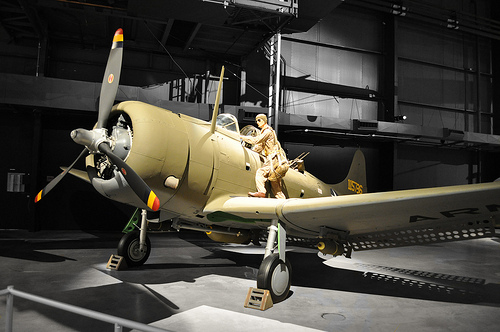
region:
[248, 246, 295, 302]
Wheel on a plane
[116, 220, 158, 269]
Black wheel on a plane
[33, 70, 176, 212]
Black prop on a plane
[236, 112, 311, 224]
Man standing on a wing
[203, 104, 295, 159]
Cockpit on a plane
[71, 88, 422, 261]
Tan plane in a hanger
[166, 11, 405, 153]
Gray wall in a hanger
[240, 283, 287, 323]
Block by a plane wheel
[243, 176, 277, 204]
Foot on a man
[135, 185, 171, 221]
Red, yellow and black on a propeller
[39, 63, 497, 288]
an old fighter jet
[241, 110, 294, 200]
a fake pilot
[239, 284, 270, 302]
a wedge preventing the plane from moving on the left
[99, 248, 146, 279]
a wedge preventing the plane from moving on the right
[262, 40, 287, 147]
a steel ladder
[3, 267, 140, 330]
some guard railing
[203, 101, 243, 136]
windshield on the plane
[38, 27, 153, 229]
propeller on the plane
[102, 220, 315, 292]
wheels on the plane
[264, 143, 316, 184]
a bag strapped to the fake pilot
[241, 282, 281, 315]
wheel stop blocks under wheel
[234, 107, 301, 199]
mannequin on an old airplane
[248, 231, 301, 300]
wheel on an old airplane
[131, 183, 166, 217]
red and yellow stripes on propellers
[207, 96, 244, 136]
windshield for cockpit on plane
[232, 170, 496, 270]
wing of airplane in hangar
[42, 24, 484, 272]
antique airplane with mannequin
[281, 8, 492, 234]
two story garage doors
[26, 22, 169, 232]
black propeller with stripes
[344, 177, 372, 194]
yellow numbers on tail fin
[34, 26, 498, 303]
an old fashioned beige plane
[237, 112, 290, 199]
statue of man climbing into plane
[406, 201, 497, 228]
large black lettering on bottom of wing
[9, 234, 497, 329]
grey floor with shadows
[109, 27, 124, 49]
red, black and yellow stripe on tip of propeller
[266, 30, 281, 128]
long silver ladder behind plane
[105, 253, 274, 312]
blocks keeping wheels in place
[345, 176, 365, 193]
yellow writing on tail fin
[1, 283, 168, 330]
part of a grey railing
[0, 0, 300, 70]
bottom of a high platform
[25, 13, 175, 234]
airplane propeller with stripes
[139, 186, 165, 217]
yellow and red stripes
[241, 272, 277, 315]
wooden wheel wedge on wheel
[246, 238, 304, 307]
landing wheel on airplane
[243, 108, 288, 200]
mannequin in a pilot uniform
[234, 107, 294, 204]
mannequin on the side of a plane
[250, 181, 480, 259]
airplane wing in a hangar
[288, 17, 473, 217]
two story garage doors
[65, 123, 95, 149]
pointy silver end of a propeller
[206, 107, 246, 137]
cockpit windshield on an antique plane